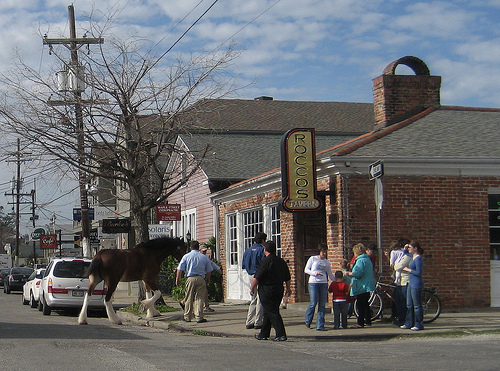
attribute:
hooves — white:
[76, 295, 173, 332]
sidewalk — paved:
[208, 298, 249, 336]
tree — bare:
[12, 42, 187, 238]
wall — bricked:
[387, 190, 481, 259]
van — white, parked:
[40, 255, 97, 312]